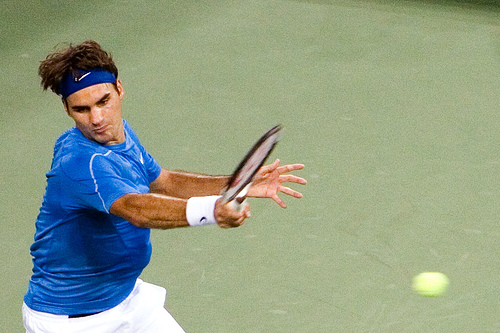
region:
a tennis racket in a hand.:
[215, 104, 317, 221]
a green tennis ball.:
[396, 251, 459, 296]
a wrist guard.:
[183, 183, 231, 240]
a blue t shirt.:
[12, 114, 166, 311]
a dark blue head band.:
[48, 33, 132, 98]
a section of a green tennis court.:
[376, 94, 426, 168]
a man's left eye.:
[85, 90, 118, 120]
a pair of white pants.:
[8, 250, 188, 332]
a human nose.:
[75, 99, 113, 125]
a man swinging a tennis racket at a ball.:
[11, 29, 333, 331]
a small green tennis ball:
[406, 272, 451, 294]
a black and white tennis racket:
[220, 108, 281, 219]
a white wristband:
[182, 189, 222, 229]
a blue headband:
[52, 66, 116, 92]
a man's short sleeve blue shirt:
[23, 134, 166, 315]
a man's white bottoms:
[24, 276, 185, 331]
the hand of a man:
[248, 162, 308, 209]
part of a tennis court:
[305, 3, 494, 158]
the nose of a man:
[90, 105, 106, 125]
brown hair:
[33, 39, 124, 94]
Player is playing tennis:
[15, 29, 317, 329]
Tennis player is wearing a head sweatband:
[38, 50, 134, 100]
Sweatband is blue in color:
[41, 45, 131, 105]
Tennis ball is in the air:
[391, 260, 466, 310]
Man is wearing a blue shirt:
[16, 115, 171, 315]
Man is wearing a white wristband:
[162, 183, 225, 248]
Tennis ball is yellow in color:
[398, 262, 460, 312]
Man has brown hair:
[31, 26, 128, 99]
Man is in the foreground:
[8, 36, 314, 330]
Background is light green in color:
[7, 8, 494, 332]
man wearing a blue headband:
[45, 49, 125, 101]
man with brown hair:
[31, 45, 122, 114]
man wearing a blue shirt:
[30, 38, 177, 331]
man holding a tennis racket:
[20, 38, 305, 313]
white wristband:
[179, 177, 235, 233]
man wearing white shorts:
[5, 42, 290, 332]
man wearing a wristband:
[22, 37, 319, 240]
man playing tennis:
[15, 27, 302, 235]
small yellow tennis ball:
[397, 262, 464, 321]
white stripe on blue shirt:
[75, 135, 125, 218]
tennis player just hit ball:
[4, 37, 476, 329]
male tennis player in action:
[19, 44, 313, 331]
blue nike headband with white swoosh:
[45, 65, 124, 94]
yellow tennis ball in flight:
[402, 258, 455, 305]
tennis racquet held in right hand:
[216, 115, 288, 233]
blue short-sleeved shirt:
[25, 124, 160, 311]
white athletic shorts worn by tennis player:
[10, 280, 187, 331]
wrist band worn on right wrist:
[180, 189, 223, 228]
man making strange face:
[37, 40, 129, 147]